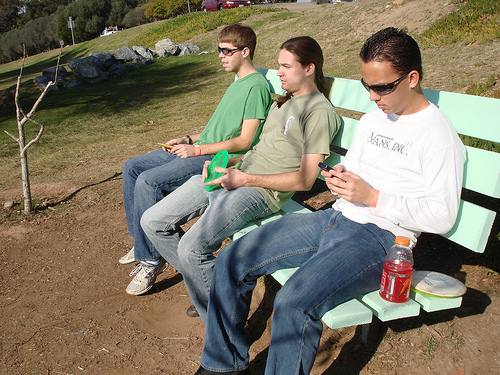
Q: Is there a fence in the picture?
A: No, there are no fences.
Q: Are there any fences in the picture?
A: No, there are no fences.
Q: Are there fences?
A: No, there are no fences.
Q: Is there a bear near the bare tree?
A: No, there is a man near the tree.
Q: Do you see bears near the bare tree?
A: No, there is a man near the tree.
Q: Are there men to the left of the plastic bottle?
A: Yes, there is a man to the left of the bottle.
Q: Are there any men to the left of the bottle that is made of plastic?
A: Yes, there is a man to the left of the bottle.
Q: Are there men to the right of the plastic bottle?
A: No, the man is to the left of the bottle.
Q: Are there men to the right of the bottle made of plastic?
A: No, the man is to the left of the bottle.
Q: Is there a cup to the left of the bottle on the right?
A: No, there is a man to the left of the bottle.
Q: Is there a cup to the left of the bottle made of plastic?
A: No, there is a man to the left of the bottle.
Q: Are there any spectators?
A: No, there are no spectators.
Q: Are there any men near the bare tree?
A: Yes, there is a man near the tree.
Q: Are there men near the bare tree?
A: Yes, there is a man near the tree.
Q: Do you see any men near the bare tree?
A: Yes, there is a man near the tree.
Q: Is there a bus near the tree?
A: No, there is a man near the tree.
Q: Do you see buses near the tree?
A: No, there is a man near the tree.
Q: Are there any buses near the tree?
A: No, there is a man near the tree.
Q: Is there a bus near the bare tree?
A: No, there is a man near the tree.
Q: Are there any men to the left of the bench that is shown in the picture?
A: Yes, there is a man to the left of the bench.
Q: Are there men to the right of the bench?
A: No, the man is to the left of the bench.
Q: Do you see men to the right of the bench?
A: No, the man is to the left of the bench.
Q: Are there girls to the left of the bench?
A: No, there is a man to the left of the bench.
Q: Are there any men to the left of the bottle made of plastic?
A: Yes, there is a man to the left of the bottle.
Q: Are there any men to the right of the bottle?
A: No, the man is to the left of the bottle.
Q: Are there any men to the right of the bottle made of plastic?
A: No, the man is to the left of the bottle.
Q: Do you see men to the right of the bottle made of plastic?
A: No, the man is to the left of the bottle.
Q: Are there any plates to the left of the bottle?
A: No, there is a man to the left of the bottle.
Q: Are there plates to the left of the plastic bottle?
A: No, there is a man to the left of the bottle.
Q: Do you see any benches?
A: Yes, there is a bench.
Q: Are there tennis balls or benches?
A: Yes, there is a bench.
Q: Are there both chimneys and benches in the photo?
A: No, there is a bench but no chimneys.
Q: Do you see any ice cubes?
A: No, there are no ice cubes.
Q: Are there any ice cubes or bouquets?
A: No, there are no ice cubes or bouquets.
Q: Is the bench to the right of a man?
A: Yes, the bench is to the right of a man.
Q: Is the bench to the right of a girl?
A: No, the bench is to the right of a man.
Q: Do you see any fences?
A: No, there are no fences.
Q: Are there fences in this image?
A: No, there are no fences.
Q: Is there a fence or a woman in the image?
A: No, there are no fences or women.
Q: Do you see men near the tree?
A: Yes, there is a man near the tree.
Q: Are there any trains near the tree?
A: No, there is a man near the tree.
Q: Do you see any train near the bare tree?
A: No, there is a man near the tree.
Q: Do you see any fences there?
A: No, there are no fences.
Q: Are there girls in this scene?
A: No, there are no girls.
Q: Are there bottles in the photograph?
A: Yes, there is a bottle.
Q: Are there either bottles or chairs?
A: Yes, there is a bottle.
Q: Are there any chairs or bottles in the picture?
A: Yes, there is a bottle.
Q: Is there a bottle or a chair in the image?
A: Yes, there is a bottle.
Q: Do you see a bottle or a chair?
A: Yes, there is a bottle.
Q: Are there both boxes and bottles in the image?
A: No, there is a bottle but no boxes.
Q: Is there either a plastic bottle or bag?
A: Yes, there is a plastic bottle.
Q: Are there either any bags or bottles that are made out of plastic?
A: Yes, the bottle is made of plastic.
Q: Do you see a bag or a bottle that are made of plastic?
A: Yes, the bottle is made of plastic.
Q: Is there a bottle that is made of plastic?
A: Yes, there is a bottle that is made of plastic.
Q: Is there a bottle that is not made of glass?
A: Yes, there is a bottle that is made of plastic.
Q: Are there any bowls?
A: No, there are no bowls.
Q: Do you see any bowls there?
A: No, there are no bowls.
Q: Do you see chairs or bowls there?
A: No, there are no bowls or chairs.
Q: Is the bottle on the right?
A: Yes, the bottle is on the right of the image.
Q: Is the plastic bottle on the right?
A: Yes, the bottle is on the right of the image.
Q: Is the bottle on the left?
A: No, the bottle is on the right of the image.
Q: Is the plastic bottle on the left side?
A: No, the bottle is on the right of the image.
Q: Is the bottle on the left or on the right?
A: The bottle is on the right of the image.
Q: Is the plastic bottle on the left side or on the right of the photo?
A: The bottle is on the right of the image.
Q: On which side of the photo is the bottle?
A: The bottle is on the right of the image.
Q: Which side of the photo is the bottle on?
A: The bottle is on the right of the image.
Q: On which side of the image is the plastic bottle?
A: The bottle is on the right of the image.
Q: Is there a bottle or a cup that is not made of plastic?
A: No, there is a bottle but it is made of plastic.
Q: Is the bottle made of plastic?
A: Yes, the bottle is made of plastic.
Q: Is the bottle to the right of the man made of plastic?
A: Yes, the bottle is made of plastic.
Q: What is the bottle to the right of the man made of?
A: The bottle is made of plastic.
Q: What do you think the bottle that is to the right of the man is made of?
A: The bottle is made of plastic.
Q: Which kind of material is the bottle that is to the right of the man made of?
A: The bottle is made of plastic.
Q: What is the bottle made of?
A: The bottle is made of plastic.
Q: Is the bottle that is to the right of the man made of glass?
A: No, the bottle is made of plastic.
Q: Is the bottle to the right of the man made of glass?
A: No, the bottle is made of plastic.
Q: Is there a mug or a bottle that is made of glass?
A: No, there is a bottle but it is made of plastic.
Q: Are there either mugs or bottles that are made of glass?
A: No, there is a bottle but it is made of plastic.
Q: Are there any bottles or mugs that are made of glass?
A: No, there is a bottle but it is made of plastic.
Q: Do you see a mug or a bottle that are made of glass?
A: No, there is a bottle but it is made of plastic.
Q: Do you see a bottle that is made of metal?
A: No, there is a bottle but it is made of plastic.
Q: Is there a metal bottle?
A: No, there is a bottle but it is made of plastic.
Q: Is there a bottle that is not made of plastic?
A: No, there is a bottle but it is made of plastic.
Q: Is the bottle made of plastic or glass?
A: The bottle is made of plastic.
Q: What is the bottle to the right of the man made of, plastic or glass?
A: The bottle is made of plastic.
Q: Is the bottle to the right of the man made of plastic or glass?
A: The bottle is made of plastic.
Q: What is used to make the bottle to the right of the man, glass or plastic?
A: The bottle is made of plastic.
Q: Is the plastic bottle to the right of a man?
A: Yes, the bottle is to the right of a man.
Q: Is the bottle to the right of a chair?
A: No, the bottle is to the right of a man.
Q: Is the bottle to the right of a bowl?
A: No, the bottle is to the right of a man.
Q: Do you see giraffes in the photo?
A: No, there are no giraffes.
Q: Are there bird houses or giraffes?
A: No, there are no giraffes or bird houses.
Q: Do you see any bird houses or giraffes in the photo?
A: No, there are no giraffes or bird houses.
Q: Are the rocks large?
A: Yes, the rocks are large.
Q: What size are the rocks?
A: The rocks are large.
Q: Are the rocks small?
A: No, the rocks are large.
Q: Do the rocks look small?
A: No, the rocks are large.